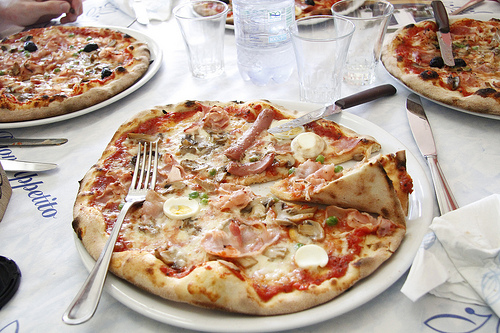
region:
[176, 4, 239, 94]
empty plastic cup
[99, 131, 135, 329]
silver fork laying on pizza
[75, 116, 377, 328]
white ceramic plates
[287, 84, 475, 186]
knives places on table for cutting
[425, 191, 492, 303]
blue and white napkin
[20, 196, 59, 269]
blue and white restaurant tablecloth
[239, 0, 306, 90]
water bottle for water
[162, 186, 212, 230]
egg yolk topping on pizza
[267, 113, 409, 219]
bent slice of pizza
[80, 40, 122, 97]
olives as toppings on pizza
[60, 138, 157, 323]
a silver dinner fork.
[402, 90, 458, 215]
a silver butter knife.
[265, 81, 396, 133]
a black steak knife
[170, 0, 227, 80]
a clear shot glass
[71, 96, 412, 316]
a large cheese pizza.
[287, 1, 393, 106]
two clear shot glasses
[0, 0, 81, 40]
a persons hand and fingers.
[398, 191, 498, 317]
a folded white napkin.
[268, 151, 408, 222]
a slice of pizza.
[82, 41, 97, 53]
a black sliced olive.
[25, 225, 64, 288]
the table cloth is white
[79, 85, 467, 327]
the pizza is on the plate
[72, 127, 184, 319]
the fork is metal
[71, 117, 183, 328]
the fork is silver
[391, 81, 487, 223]
the knife is metal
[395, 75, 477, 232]
the metal is silver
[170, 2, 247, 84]
the glass is clear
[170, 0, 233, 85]
the cup is empty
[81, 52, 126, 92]
the olive is black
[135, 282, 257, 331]
the plate is white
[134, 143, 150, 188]
prongs on metal fork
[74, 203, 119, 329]
long handle of a metal fok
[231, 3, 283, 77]
a plastic bottle of water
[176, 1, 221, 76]
an empty glass sitting on the table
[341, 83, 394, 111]
brown wooden handle of a knife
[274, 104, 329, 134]
metal blade of a knife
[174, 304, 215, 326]
the edge of a white plate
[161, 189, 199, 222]
a white mushroom on a pizza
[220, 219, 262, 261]
Canadian bacon on pizza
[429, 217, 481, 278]
a white napkin on the side of the plate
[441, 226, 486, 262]
part of a tissue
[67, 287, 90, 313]
handle of a fork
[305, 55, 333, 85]
part of a glass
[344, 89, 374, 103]
wooden handle of a knife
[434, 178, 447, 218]
metal hand of a knife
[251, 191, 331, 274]
part of a pizza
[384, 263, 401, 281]
part of a white dish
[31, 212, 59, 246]
part of a white cloth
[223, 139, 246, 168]
part of a sausage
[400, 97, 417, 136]
edge of a knife